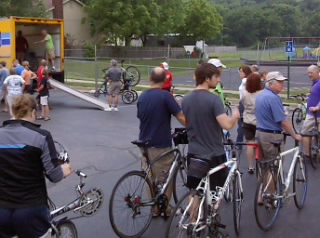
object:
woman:
[1, 93, 72, 236]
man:
[103, 59, 125, 112]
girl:
[33, 70, 50, 121]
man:
[32, 29, 56, 72]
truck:
[0, 15, 119, 111]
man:
[16, 30, 30, 64]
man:
[0, 59, 10, 112]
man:
[12, 59, 24, 76]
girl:
[21, 60, 37, 94]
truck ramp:
[48, 77, 111, 110]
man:
[37, 59, 47, 88]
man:
[299, 64, 319, 161]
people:
[182, 63, 236, 233]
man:
[135, 66, 185, 220]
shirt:
[137, 87, 182, 148]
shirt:
[106, 66, 122, 80]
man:
[3, 67, 26, 119]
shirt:
[4, 75, 25, 95]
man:
[251, 71, 302, 206]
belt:
[256, 126, 282, 135]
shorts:
[139, 142, 177, 189]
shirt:
[306, 79, 319, 117]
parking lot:
[0, 87, 319, 237]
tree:
[83, 0, 160, 58]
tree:
[142, 0, 223, 59]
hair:
[13, 96, 37, 118]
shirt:
[42, 34, 54, 51]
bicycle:
[166, 141, 260, 238]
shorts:
[2, 205, 54, 237]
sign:
[285, 41, 293, 52]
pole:
[287, 55, 290, 101]